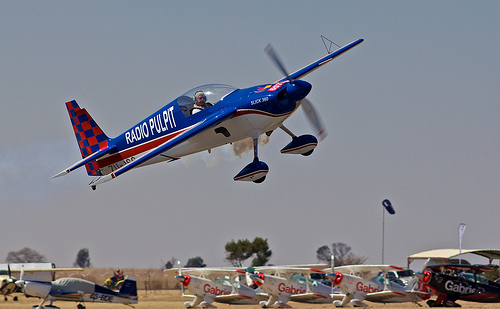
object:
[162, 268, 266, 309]
plane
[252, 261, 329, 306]
plane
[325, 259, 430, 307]
plane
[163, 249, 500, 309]
plane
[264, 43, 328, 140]
propeller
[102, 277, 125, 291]
jacket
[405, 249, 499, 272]
canopy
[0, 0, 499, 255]
background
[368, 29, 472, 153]
boy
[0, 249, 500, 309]
aircraft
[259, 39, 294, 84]
propeller blade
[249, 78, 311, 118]
nose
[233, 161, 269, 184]
blue paint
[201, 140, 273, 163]
white clouds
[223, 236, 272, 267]
tree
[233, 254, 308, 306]
plane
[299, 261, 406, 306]
plane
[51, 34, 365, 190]
aircraft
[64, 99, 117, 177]
tail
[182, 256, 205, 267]
tree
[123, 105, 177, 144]
radio pulpit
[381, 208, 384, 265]
pole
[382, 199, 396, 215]
wind sock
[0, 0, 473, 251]
clouds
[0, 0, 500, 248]
sky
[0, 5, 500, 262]
blue sky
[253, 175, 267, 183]
wheel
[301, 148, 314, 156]
wheel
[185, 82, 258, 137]
cockpit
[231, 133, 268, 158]
smoke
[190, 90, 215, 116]
pilot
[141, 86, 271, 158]
paint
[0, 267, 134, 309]
structure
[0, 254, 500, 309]
field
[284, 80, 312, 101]
nose hub